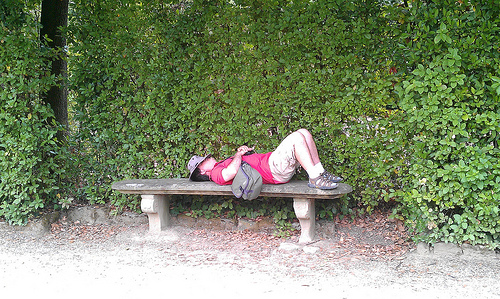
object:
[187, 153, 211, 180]
hat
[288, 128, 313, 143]
knee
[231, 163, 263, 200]
bag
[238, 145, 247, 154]
hands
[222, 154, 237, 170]
chest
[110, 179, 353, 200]
concrete slab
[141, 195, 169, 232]
concrete leg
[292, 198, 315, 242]
concrete leg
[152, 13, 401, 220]
bushes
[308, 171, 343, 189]
brown sandals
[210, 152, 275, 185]
shirt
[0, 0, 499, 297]
garden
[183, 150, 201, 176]
hat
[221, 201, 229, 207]
leaves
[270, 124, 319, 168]
legs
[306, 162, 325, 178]
socks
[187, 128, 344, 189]
man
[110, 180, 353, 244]
bench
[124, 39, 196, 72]
foliage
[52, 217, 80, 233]
leaves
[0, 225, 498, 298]
ground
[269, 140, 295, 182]
shorts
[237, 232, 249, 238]
leaves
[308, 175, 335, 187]
feet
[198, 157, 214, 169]
face